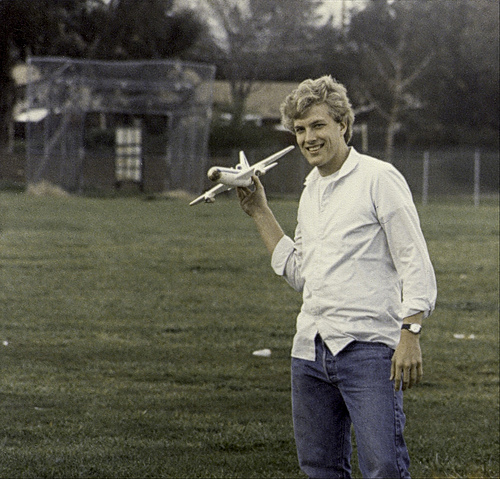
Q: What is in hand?
A: A model airplane.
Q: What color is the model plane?
A: It is white.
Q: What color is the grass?
A: Green.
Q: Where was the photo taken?
A: In the outdoors.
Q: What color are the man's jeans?
A: Blue.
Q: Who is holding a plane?
A: A man.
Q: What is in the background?
A: Trees.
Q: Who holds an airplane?
A: The man.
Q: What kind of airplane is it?
A: A model.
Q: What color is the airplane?
A: White.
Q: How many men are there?
A: One.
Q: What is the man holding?
A: Airplane.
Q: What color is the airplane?
A: White.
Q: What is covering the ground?
A: Grass.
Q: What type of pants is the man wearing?
A: Jeans.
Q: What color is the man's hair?
A: Blonde.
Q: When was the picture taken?
A: Daytime.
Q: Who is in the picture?
A: A man.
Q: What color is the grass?
A: Green.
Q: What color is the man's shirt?
A: White.